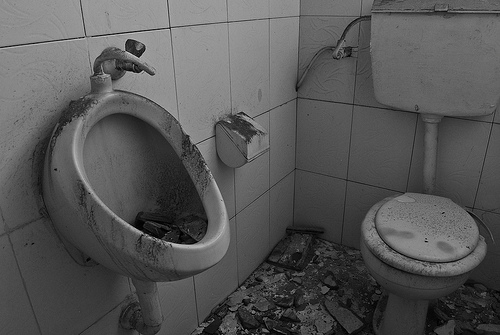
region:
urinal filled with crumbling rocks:
[49, 35, 231, 279]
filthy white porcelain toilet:
[365, 181, 487, 333]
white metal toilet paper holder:
[213, 105, 275, 167]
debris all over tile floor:
[207, 212, 366, 334]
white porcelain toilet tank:
[361, 0, 498, 125]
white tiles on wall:
[170, 20, 295, 258]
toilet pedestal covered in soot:
[365, 280, 428, 334]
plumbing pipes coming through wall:
[292, 10, 372, 89]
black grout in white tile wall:
[290, 95, 300, 230]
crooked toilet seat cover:
[371, 177, 478, 268]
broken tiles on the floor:
[274, 279, 335, 323]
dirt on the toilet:
[371, 222, 402, 262]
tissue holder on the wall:
[217, 111, 279, 175]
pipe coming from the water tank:
[405, 116, 461, 191]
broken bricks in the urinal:
[150, 201, 217, 249]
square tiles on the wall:
[167, 24, 277, 77]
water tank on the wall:
[369, 5, 499, 137]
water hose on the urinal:
[92, 49, 162, 71]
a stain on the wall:
[257, 74, 268, 114]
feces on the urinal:
[121, 222, 174, 269]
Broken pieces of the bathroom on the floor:
[251, 281, 353, 333]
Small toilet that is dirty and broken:
[357, 189, 495, 333]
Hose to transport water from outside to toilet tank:
[292, 13, 375, 97]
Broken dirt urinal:
[24, 41, 233, 333]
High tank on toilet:
[367, 2, 498, 124]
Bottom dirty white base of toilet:
[362, 190, 495, 333]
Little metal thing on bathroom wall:
[215, 112, 271, 169]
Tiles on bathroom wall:
[161, 11, 286, 121]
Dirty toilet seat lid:
[374, 189, 481, 266]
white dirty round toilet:
[358, 181, 498, 329]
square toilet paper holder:
[225, 103, 272, 171]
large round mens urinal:
[36, 64, 236, 312]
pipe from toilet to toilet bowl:
[408, 109, 448, 204]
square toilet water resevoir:
[368, 8, 498, 133]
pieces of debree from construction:
[285, 227, 313, 334]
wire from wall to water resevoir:
[302, 20, 356, 112]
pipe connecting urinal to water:
[115, 276, 180, 331]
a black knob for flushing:
[95, 35, 176, 80]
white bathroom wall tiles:
[186, 34, 263, 95]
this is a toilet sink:
[355, 185, 489, 304]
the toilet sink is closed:
[360, 193, 484, 311]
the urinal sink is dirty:
[28, 34, 228, 331]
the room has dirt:
[266, 246, 354, 332]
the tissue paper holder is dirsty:
[217, 111, 271, 168]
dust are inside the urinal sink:
[143, 200, 193, 231]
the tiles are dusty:
[171, 17, 283, 106]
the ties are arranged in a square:
[165, 21, 267, 101]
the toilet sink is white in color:
[362, 205, 457, 270]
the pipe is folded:
[82, 48, 151, 88]